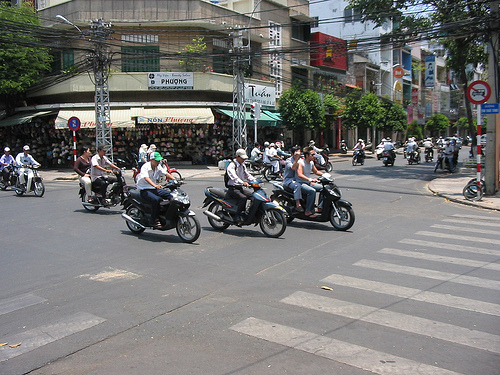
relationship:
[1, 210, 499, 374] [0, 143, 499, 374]
lines on street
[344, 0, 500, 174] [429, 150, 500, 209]
tree on sidewalk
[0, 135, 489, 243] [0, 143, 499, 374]
motorcyclists on street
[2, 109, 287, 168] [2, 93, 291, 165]
merchandise in store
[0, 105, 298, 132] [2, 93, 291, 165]
awnings over store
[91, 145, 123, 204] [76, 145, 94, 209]
biker with a passenger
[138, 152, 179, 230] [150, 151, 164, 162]
man with a hat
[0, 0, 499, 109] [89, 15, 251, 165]
wires connecting structures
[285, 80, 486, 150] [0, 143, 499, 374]
trees lined up near street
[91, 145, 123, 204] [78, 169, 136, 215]
biker on a motorcycle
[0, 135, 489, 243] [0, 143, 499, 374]
motorcyclists riding on street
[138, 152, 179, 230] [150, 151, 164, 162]
man wearing a green hat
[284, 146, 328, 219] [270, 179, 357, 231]
people on a motorcycle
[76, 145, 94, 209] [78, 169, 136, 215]
passenger on motorcycle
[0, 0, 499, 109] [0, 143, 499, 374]
wires over street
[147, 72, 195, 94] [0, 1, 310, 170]
sign on building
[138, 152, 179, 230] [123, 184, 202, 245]
man on a motorcycle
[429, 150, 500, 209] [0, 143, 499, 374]
sidewalk near street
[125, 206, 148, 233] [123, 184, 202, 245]
wheel of motorcycle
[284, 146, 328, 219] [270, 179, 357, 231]
people riding a motorcycle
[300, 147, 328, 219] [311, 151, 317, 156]
man wearing sunglasses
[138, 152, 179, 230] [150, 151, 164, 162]
man with a white hat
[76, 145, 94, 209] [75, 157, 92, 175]
passenger in a brown shirt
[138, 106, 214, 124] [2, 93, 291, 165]
awning over store